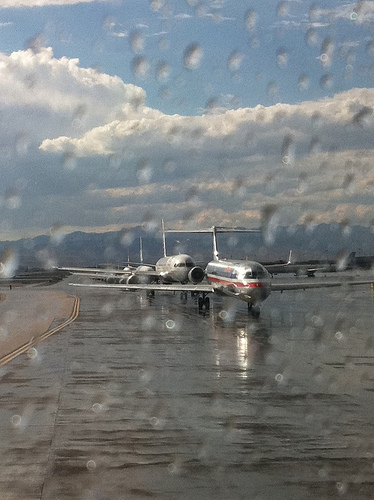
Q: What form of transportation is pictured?
A: Airplane.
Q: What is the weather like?
A: Rainy.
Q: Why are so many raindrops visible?
A: They are on the camera lens.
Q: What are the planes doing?
A: Sitting on the runway.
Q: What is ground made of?
A: Cement.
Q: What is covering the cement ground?
A: Water.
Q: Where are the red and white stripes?
A: On the planes.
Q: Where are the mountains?
A: In the background behind the planes.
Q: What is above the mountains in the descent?
A: Heavy white clouds.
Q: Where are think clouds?
A: Lower part of sky.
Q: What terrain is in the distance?
A: Mountains.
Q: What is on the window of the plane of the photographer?
A: Water droplets.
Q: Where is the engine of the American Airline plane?
A: Back of fuselage.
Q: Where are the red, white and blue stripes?
A: On the front plane.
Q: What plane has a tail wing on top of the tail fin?
A: Front plane.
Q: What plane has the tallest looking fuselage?
A: Second plane.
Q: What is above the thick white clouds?
A: Blue sky.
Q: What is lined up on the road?
A: Planes.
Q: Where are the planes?
A: On the ground.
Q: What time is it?
A: Afternoon.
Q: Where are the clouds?
A: In the sky.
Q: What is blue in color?
A: The sky.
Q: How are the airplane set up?
A: In a row.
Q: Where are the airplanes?
A: In the rain.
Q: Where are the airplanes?
A: In the runway.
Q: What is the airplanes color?
A: Silver.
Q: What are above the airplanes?
A: Clouds.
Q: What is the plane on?
A: Wet ground.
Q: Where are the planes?
A: Runway.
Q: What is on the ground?
A: Rain water.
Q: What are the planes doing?
A: Getting ready for takeoff.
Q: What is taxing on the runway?
A: A red white and blue jet.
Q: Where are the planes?
A: On a wet tarmac.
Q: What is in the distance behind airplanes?
A: Tall mountains.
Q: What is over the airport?
A: Cloudy blue sky.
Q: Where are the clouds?
A: In the sky.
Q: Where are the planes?
A: On a runway.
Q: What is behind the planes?
A: The mountains.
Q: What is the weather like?
A: Raining.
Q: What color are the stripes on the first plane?
A: Blue, white and red.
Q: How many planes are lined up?
A: At least four.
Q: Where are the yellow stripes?
A: Along the side of the runway on the left.